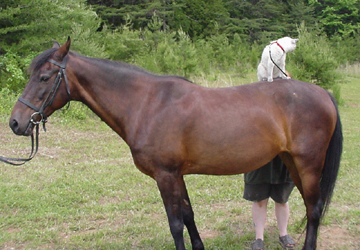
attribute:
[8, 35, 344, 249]
horse — brown, standing, held, large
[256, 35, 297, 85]
cat — white, seated, small, seating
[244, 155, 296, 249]
person — standing, obscured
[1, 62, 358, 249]
grass — green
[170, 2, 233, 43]
tree — green, growing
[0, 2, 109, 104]
tree — green, growing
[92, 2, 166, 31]
tree — green, growing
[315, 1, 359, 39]
tree — green, growing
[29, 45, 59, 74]
hair — long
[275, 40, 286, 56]
collar — red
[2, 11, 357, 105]
vegetation — growing